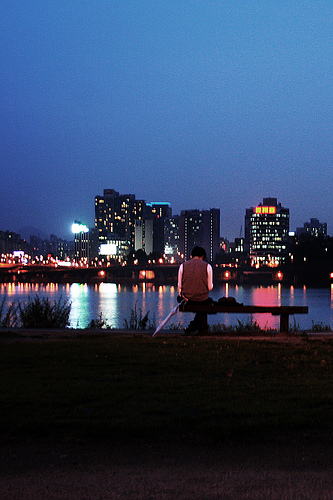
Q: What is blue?
A: Sky.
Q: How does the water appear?
A: Calm.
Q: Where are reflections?
A: On the water.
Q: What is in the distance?
A: Buildings.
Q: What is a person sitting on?
A: A bench.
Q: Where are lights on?
A: In the buildings.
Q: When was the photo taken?
A: Dusk.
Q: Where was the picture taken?
A: On a hike and bike trail.